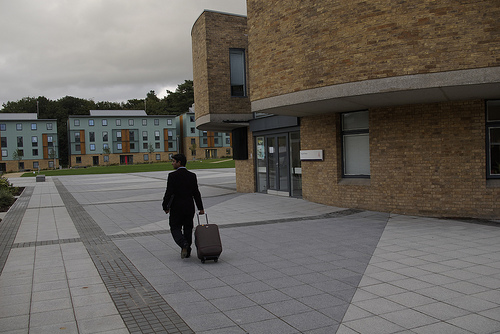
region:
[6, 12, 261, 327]
man walking to building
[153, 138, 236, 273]
man dragging a suitcase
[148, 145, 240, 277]
man wearing a black suit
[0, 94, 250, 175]
building with many windows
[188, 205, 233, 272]
suit case is black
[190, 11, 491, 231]
door is in building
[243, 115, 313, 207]
the door is black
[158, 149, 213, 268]
the suit is black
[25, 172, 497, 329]
the sidewalk is gray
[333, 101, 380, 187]
the window is closed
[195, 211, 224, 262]
brown luggage has wheels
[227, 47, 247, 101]
window in brick building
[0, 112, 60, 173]
coloful four-story building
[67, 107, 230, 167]
colorful four-story building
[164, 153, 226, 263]
man is draggin suitcase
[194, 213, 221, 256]
suitcase is rolling on wheels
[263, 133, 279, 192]
door is glass with metal trim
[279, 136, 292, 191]
door is glass with metal trim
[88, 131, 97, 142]
window is on third floor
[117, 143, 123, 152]
window is on second floor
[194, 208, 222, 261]
luggage is brown with wheels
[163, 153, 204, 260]
man is pulling luggage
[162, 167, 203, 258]
suit is black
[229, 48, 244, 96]
window on second floor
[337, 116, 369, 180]
window in brick building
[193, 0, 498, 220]
two-story brick building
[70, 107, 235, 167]
large four-story building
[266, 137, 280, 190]
door is glas with gray trim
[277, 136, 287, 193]
door is glass with metal frame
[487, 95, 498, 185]
window in first floor of building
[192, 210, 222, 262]
A grey roller suitcase.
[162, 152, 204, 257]
A man walking with a suitcase.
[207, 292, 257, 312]
A blue-gray outdoor tile.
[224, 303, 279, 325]
A blue-gray outdoor tile.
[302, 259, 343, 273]
A blue-gray outdoor tile.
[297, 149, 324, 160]
A sign on a building.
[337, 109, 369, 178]
A window on a building.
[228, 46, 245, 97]
A window on a building.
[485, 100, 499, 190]
A window on a building.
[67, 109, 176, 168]
An ugly building.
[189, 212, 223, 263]
the piece of luggage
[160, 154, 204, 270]
the man pulling the luggage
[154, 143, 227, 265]
the man and his luggage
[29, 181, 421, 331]
the long concrete walkway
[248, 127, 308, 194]
the doors on the building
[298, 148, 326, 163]
sign on the outside of the building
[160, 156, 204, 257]
the man in the suit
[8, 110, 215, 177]
the buildings in the background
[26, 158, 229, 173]
grassy area in front of the apartment buildings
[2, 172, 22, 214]
bushes across from the entrance